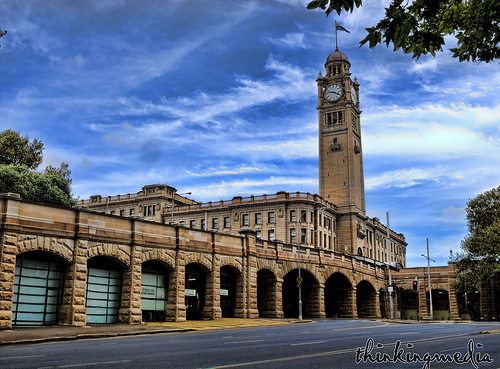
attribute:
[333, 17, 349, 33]
flag — waving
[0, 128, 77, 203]
trees — fluffy, green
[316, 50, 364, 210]
tower — tall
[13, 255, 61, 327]
shutter — down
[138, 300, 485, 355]
street — grey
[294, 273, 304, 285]
sign — yellow, metal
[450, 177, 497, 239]
leaves — green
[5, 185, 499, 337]
building — brown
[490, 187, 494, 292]
leaves — green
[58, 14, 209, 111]
sky — blue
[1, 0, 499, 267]
sky — blue, cloudy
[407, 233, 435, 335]
light — red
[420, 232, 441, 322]
pole — metal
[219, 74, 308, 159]
clouds — white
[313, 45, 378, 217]
clock tower — tall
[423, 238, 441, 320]
pole — silver, metal